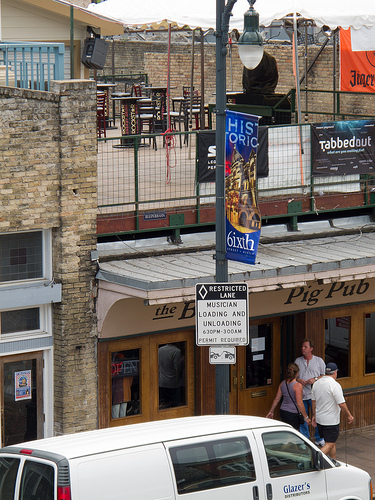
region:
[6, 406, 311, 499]
white van parked on a sidewalk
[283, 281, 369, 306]
title of a bar in black letters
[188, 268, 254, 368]
traffic signs on a pole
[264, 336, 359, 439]
people walking down the street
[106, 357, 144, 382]
a half-working open sign in a window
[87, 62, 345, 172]
outside upper patio of a bar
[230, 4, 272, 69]
street light on a lamp post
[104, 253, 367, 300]
awning of a bar/pub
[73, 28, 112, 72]
speaker for music on outdoor deck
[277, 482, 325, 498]
company name on the side of a van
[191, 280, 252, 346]
a black and white sign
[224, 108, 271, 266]
a large blue flag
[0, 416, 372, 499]
part of a white van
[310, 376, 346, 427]
a man's white shirt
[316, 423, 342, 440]
a man's black shorts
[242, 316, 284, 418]
part of a brown door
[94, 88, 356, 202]
the roof top of a building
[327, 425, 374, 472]
part of a sidewalk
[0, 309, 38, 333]
the window of a building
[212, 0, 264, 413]
part of a large gray light pole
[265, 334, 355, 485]
Three people in front of street side business.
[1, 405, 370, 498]
White van on street in front of business.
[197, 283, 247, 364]
Restricted parking road sign.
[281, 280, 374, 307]
Restaurant signage on pub.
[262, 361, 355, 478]
Two people walking down sidewalk.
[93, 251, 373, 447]
Pig pub business front.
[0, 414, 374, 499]
White Glazer's van in front of building.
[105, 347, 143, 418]
Partially lit lighted open sign.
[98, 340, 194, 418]
Windows of Pig Pub.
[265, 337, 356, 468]
Three people in front of a local business.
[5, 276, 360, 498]
a white van parked next a road sign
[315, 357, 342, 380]
a man wearing a blue hat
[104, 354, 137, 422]
someone standing in a window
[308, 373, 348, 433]
a man wearing a white shirt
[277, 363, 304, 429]
a woman carrying a black shoulder bag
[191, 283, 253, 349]
a black and white road sign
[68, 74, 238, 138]
several table and chairs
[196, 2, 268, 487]
a street lamp on a tall pole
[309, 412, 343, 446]
a man wearing black shorts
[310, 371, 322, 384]
a man wearing a wrist watch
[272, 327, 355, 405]
three people in the photo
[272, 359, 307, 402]
woman in the photo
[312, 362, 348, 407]
man with a hat on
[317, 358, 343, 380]
hat on the man's head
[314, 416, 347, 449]
shorts on the man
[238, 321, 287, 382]
window on the door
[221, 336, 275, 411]
doors next to the man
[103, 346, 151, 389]
sign in the window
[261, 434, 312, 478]
window of a van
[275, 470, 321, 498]
word on side of van